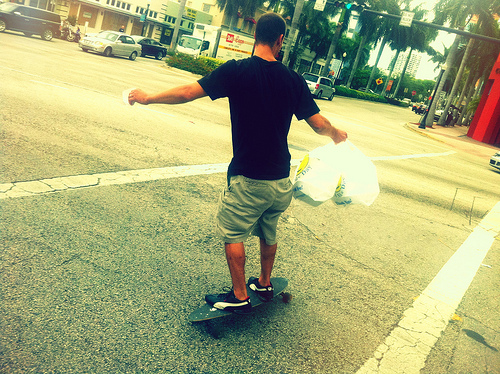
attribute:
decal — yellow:
[287, 146, 360, 214]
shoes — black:
[203, 275, 275, 315]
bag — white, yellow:
[290, 142, 342, 207]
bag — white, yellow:
[329, 138, 381, 209]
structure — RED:
[435, 47, 499, 142]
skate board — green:
[187, 274, 292, 333]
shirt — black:
[196, 54, 322, 179]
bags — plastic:
[292, 140, 379, 205]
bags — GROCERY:
[295, 143, 382, 210]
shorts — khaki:
[215, 172, 294, 247]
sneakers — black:
[204, 275, 275, 314]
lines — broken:
[348, 195, 497, 371]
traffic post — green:
[323, 1, 497, 47]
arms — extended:
[110, 10, 380, 195]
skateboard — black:
[187, 273, 291, 324]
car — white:
[74, 27, 144, 59]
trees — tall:
[318, 10, 439, 98]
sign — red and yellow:
[368, 74, 386, 88]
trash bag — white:
[294, 151, 376, 206]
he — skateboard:
[212, 10, 323, 285]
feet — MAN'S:
[215, 282, 298, 323]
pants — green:
[212, 174, 300, 249]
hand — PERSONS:
[326, 128, 349, 144]